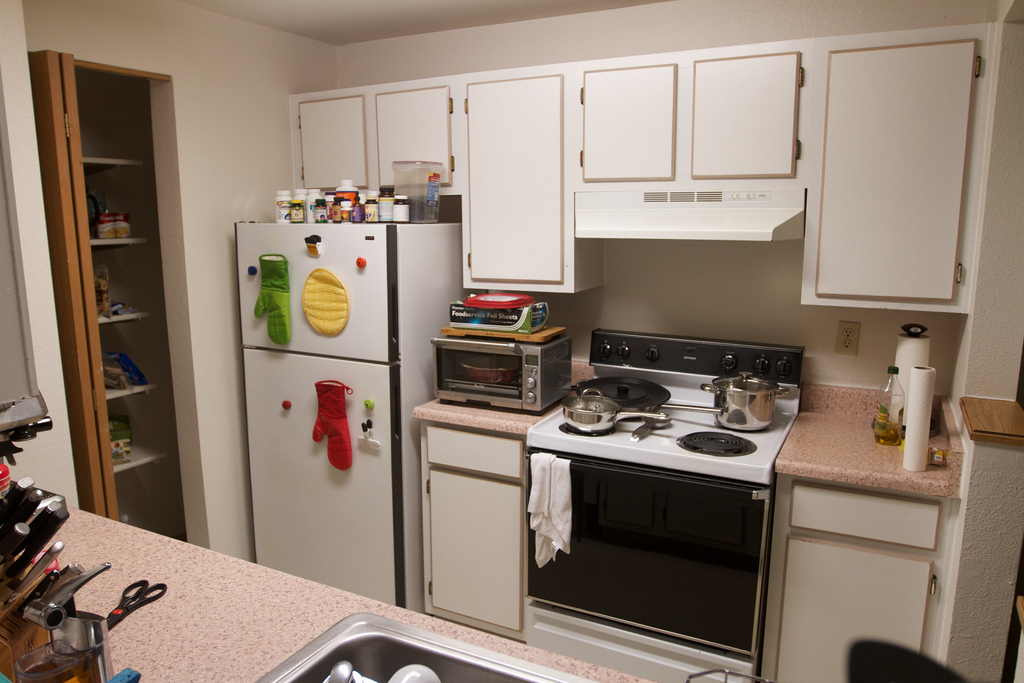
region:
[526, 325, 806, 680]
Black and white oven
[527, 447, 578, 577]
White hand towel hanging from oven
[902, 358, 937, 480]
Roll of paper towels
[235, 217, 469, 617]
White refrigerator against wall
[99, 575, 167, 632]
Pair of black scissors on countertop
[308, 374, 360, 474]
Red oven mitt on fridge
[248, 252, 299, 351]
Lime green oven mitt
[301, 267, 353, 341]
Yellow hot pad on fridge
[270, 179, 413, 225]
Row of medicine bottles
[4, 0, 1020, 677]
interior of residential kitchen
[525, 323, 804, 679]
pots on stove top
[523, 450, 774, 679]
towel hanging on oven door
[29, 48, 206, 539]
open door of closet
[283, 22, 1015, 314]
closed doors of cupboards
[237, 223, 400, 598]
oven mitts on refrigerator doors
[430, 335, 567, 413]
front of toaster oven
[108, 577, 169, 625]
black handles of scissors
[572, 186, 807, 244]
front of range hood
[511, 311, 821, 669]
An oven and stove in the middle of the cabinetry.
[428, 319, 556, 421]
A microwave oven on the countertop.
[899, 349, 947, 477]
An almost empty roll of paper towels.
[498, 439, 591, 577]
A white dish towel hanging from the oven handle.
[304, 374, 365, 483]
A red oven mitt on the refrigerator door.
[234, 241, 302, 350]
A green oven mitt on the freezer door.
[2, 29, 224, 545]
A narrow pantry at the end of the kitchen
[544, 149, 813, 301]
The exhaust hood above the stove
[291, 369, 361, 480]
a red oven mitt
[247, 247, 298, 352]
a green oven mitt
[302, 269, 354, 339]
a yellow round pot holder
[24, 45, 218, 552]
an open pantry of food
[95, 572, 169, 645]
scissors with a black handle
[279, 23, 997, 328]
white wall kitchen cabinets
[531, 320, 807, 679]
a white and black kitchen range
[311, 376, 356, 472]
Red oven glove on refrigerator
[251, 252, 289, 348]
green oven glove on refrigerator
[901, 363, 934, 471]
white paper towel roll on counter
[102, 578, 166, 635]
black scissors on counter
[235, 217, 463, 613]
white refrigerator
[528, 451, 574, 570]
white towel hanging on oven door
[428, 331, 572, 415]
silver microwave oven on counter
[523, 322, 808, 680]
black and white oven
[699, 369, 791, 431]
silver pot on stove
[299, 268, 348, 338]
yellow pot holder on refrigerator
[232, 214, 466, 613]
red oven mit hanging on refrigerator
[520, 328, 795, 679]
stove in the kitchen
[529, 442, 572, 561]
the towel is white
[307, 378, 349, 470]
glove on the fridge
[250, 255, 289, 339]
glove on the fridge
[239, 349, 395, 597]
the door is closed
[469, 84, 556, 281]
the door is closed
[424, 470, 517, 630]
the door is closed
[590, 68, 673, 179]
the door is closed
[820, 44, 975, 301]
the door is closed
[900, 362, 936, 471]
Thinner white roll of paper towels.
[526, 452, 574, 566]
White towel on an oven front.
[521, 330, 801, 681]
Black and white oven.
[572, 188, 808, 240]
White metal vent hood above the stove.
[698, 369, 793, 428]
Large covered silver pot on the stove.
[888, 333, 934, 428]
Larger white roll of paper towels.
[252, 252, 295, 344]
Green oven glove on the fridge.